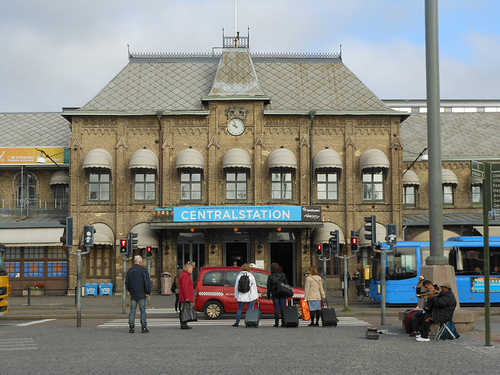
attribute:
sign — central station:
[167, 198, 306, 224]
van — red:
[191, 262, 321, 318]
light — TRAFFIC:
[109, 234, 148, 256]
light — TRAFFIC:
[355, 192, 391, 269]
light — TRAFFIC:
[352, 205, 376, 262]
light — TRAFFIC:
[332, 211, 381, 269]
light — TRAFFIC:
[343, 209, 389, 268]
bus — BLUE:
[375, 240, 483, 270]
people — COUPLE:
[404, 272, 444, 332]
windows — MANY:
[86, 151, 389, 204]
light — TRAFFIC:
[361, 210, 390, 247]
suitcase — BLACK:
[268, 304, 302, 334]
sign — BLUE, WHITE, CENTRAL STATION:
[165, 197, 301, 226]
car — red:
[195, 261, 313, 321]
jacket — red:
[172, 264, 202, 307]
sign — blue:
[168, 199, 304, 226]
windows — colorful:
[6, 243, 64, 273]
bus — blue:
[366, 232, 498, 313]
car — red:
[195, 257, 320, 322]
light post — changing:
[59, 223, 95, 324]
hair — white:
[133, 250, 140, 262]